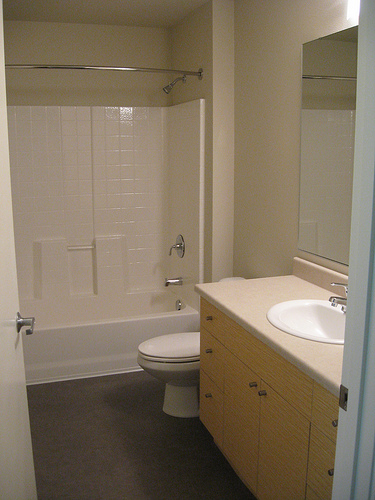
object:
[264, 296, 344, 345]
sink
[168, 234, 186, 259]
shower knob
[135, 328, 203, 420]
toilet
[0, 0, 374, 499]
bathroom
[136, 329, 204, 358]
toilet lid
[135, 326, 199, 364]
toilet seat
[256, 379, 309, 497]
door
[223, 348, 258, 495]
door